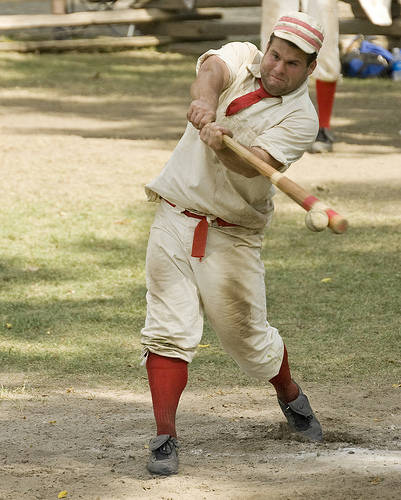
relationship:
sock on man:
[126, 357, 204, 426] [130, 18, 350, 265]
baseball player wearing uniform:
[138, 10, 326, 474] [125, 39, 320, 386]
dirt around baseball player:
[9, 390, 125, 494] [138, 10, 326, 474]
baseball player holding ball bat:
[138, 10, 326, 474] [221, 132, 350, 235]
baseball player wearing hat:
[138, 10, 326, 474] [261, 1, 333, 64]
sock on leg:
[146, 353, 189, 438] [142, 241, 204, 474]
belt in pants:
[157, 192, 267, 263] [145, 193, 292, 382]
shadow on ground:
[30, 247, 138, 355] [0, 51, 399, 497]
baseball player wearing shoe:
[138, 10, 326, 474] [146, 434, 178, 473]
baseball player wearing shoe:
[138, 10, 326, 474] [277, 378, 322, 442]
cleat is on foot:
[129, 424, 190, 474] [146, 429, 180, 477]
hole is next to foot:
[267, 422, 366, 449] [270, 370, 326, 445]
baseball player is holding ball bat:
[138, 10, 326, 474] [221, 132, 350, 235]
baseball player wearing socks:
[138, 10, 326, 474] [61, 325, 257, 497]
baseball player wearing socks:
[138, 10, 326, 474] [141, 348, 299, 432]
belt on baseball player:
[162, 197, 241, 255] [138, 10, 326, 474]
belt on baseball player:
[157, 192, 267, 263] [138, 10, 326, 474]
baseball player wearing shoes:
[138, 10, 326, 474] [134, 389, 323, 473]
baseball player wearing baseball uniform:
[138, 10, 326, 474] [141, 12, 320, 376]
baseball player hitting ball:
[138, 10, 326, 474] [301, 204, 331, 235]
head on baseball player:
[238, 12, 337, 95] [138, 10, 326, 474]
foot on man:
[141, 406, 174, 477] [125, 48, 355, 462]